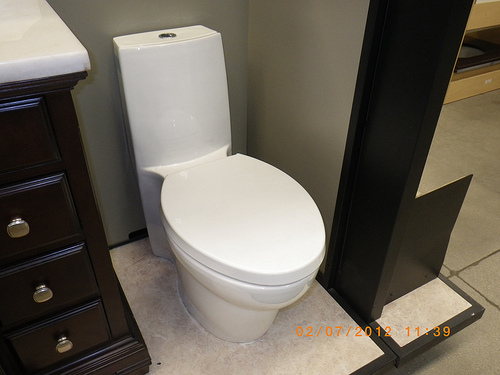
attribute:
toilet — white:
[113, 23, 328, 347]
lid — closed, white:
[160, 152, 327, 275]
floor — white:
[107, 229, 381, 373]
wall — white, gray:
[54, 1, 370, 276]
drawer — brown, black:
[3, 172, 83, 257]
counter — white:
[1, 1, 92, 85]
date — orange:
[294, 321, 453, 339]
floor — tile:
[373, 88, 499, 373]